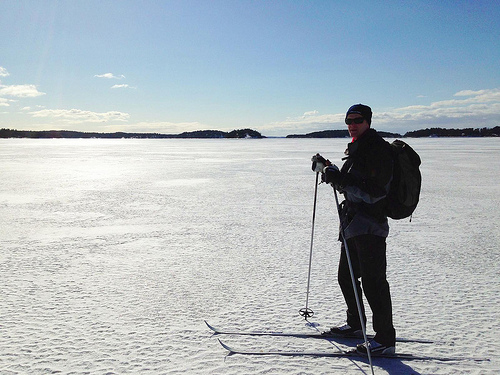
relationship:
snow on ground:
[124, 138, 217, 192] [53, 132, 248, 327]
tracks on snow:
[144, 296, 241, 348] [124, 138, 217, 192]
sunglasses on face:
[326, 111, 379, 131] [337, 109, 374, 141]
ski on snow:
[197, 288, 343, 349] [124, 138, 217, 192]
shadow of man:
[339, 323, 445, 369] [296, 80, 429, 336]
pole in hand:
[297, 159, 327, 310] [304, 143, 333, 179]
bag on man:
[376, 131, 451, 274] [296, 80, 429, 336]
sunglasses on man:
[326, 111, 379, 131] [296, 80, 429, 336]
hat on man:
[338, 96, 377, 123] [296, 80, 429, 336]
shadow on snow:
[339, 323, 445, 369] [124, 138, 217, 192]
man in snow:
[296, 80, 429, 336] [124, 138, 217, 192]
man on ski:
[296, 80, 429, 336] [197, 288, 343, 349]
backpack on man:
[389, 132, 429, 245] [296, 80, 429, 336]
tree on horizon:
[24, 109, 270, 144] [1, 119, 482, 152]